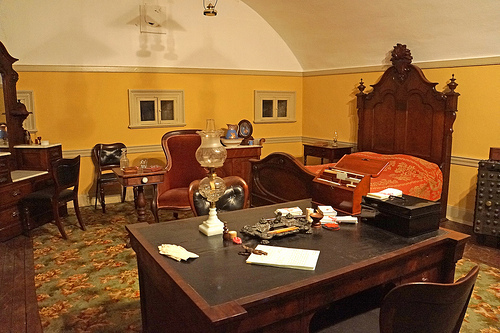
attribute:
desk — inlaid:
[121, 200, 470, 331]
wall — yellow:
[80, 73, 104, 143]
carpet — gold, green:
[0, 166, 499, 330]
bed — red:
[253, 38, 453, 208]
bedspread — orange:
[297, 147, 447, 208]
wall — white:
[16, 4, 306, 67]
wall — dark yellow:
[35, 76, 128, 135]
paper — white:
[243, 241, 323, 271]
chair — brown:
[381, 265, 481, 331]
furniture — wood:
[22, 137, 95, 238]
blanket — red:
[394, 159, 424, 201]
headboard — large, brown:
[335, 36, 453, 185]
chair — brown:
[18, 155, 84, 243]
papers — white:
[228, 240, 332, 277]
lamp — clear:
[190, 114, 232, 239]